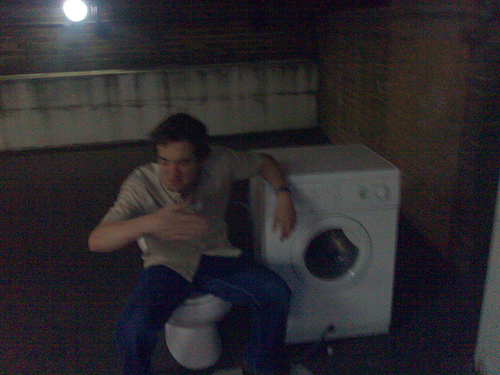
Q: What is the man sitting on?
A: Toilet.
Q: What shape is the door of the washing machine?
A: Circle.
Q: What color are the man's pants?
A: Blue.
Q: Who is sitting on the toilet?
A: A man.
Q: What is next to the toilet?
A: Washing machine.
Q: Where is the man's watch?
A: Left wrist.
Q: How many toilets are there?
A: One.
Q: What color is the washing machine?
A: White.